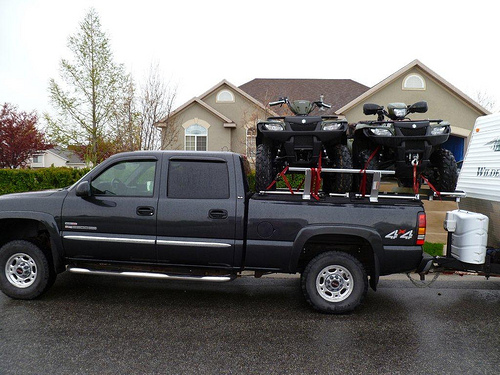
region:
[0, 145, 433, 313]
The truck is black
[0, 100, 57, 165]
Red leaves on a tree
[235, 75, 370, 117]
The roof of a house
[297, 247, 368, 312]
A black rubber tire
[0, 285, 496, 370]
The road appears to be wet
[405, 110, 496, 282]
A white trailer attached to back of a truck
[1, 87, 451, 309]
Two tractors on back of the truck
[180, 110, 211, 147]
A window on a house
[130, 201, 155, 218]
Handle of a truck door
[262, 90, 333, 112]
The handlebars of a tractor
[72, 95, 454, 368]
a truck on the road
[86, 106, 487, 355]
a truck on the street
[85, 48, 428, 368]
a gray truck on the road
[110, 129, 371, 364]
a large truck on the road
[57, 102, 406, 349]
a large truck on the street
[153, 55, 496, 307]
four wheelers on the truck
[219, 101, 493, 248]
four wheelers on a large truck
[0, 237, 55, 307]
front wheel of car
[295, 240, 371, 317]
back wheel of car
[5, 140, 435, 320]
a black pickup on road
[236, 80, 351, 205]
a motorcycle over a pickup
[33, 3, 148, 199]
the tree is green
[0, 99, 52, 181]
the trees is red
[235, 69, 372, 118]
the roof is black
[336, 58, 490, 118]
small window below roof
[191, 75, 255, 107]
small window below roof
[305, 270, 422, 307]
black tires on truck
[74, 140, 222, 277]
black doors on truck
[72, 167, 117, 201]
black mirror on door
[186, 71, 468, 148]
tan walls on house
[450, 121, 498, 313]
rv attached to truck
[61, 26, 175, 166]
thin trees near house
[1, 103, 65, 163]
red tree left of house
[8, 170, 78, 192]
green bushes behind truck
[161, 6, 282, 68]
sky is grey and cloudy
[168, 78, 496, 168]
a tan house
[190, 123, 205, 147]
a window on the house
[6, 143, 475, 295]
a black truck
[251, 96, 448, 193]
four wheelers on the truck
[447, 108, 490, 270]
a white trailer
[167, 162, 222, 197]
a window on the truck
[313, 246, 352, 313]
a tire on the truck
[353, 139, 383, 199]
red straps on the four wheelers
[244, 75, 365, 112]
the roof of the house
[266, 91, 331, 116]
the handlebars on the four wheeler